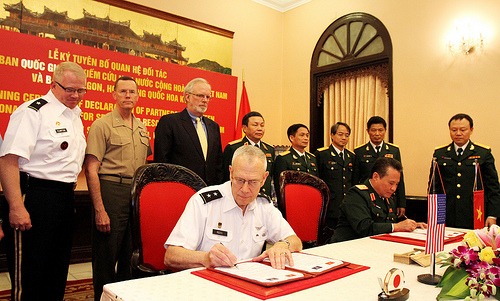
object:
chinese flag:
[471, 188, 485, 229]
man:
[164, 146, 304, 273]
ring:
[282, 253, 287, 256]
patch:
[217, 222, 222, 229]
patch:
[199, 189, 223, 204]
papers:
[216, 260, 304, 282]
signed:
[226, 262, 255, 271]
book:
[213, 252, 344, 286]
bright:
[438, 14, 494, 52]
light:
[447, 13, 483, 46]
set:
[313, 11, 398, 146]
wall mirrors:
[311, 60, 392, 152]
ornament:
[376, 269, 408, 300]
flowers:
[449, 245, 479, 268]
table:
[97, 218, 499, 300]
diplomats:
[154, 78, 225, 179]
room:
[4, 1, 500, 301]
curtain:
[325, 75, 393, 166]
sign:
[0, 0, 237, 168]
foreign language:
[0, 49, 227, 105]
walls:
[285, 1, 499, 196]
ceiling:
[1, 2, 498, 37]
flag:
[427, 195, 447, 252]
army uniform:
[2, 91, 87, 300]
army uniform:
[163, 180, 297, 267]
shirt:
[0, 91, 88, 184]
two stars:
[206, 192, 218, 198]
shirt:
[85, 106, 153, 180]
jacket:
[154, 107, 228, 192]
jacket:
[224, 136, 277, 205]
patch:
[56, 121, 62, 126]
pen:
[220, 241, 241, 270]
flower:
[448, 245, 480, 268]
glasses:
[234, 177, 263, 185]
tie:
[456, 148, 463, 160]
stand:
[416, 253, 447, 287]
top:
[306, 10, 396, 73]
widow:
[318, 68, 391, 148]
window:
[332, 23, 350, 61]